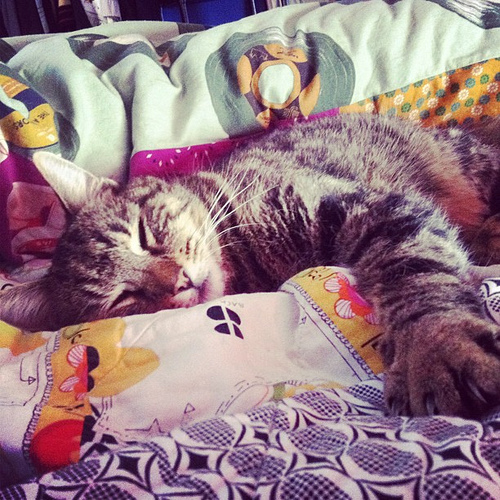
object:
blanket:
[0, 266, 391, 479]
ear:
[30, 144, 108, 212]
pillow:
[1, 0, 500, 275]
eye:
[135, 206, 157, 254]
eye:
[106, 279, 141, 309]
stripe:
[349, 56, 500, 141]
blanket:
[0, 0, 499, 499]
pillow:
[3, 383, 500, 498]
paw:
[378, 300, 500, 426]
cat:
[1, 109, 499, 425]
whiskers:
[199, 158, 264, 252]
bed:
[1, 0, 500, 497]